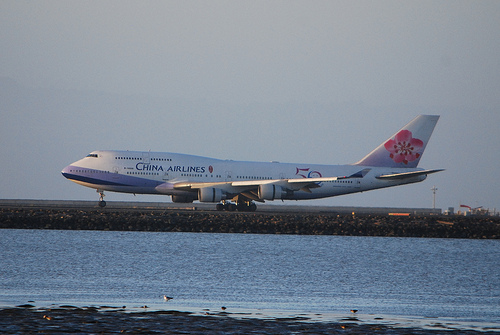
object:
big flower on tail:
[382, 129, 425, 166]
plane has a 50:
[282, 159, 333, 201]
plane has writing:
[118, 151, 228, 189]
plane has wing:
[125, 144, 386, 216]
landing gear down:
[81, 180, 276, 214]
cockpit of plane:
[83, 153, 99, 159]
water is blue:
[106, 233, 204, 301]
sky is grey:
[163, 25, 288, 114]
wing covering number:
[270, 162, 348, 194]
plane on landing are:
[47, 113, 454, 213]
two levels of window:
[87, 154, 298, 184]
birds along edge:
[346, 306, 364, 313]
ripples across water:
[61, 252, 168, 285]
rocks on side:
[10, 208, 34, 231]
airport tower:
[428, 182, 441, 209]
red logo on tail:
[377, 127, 438, 170]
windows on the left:
[60, 139, 131, 199]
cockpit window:
[88, 154, 98, 158]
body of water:
[162, 240, 267, 290]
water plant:
[461, 205, 493, 238]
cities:
[374, 189, 500, 222]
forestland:
[12, 193, 76, 229]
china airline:
[133, 161, 207, 173]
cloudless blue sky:
[105, 16, 286, 131]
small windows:
[114, 156, 118, 160]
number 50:
[294, 166, 324, 188]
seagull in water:
[158, 288, 181, 305]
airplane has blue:
[57, 138, 157, 227]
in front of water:
[37, 127, 142, 300]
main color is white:
[218, 163, 286, 173]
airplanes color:
[396, 132, 411, 140]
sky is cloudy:
[172, 43, 301, 146]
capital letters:
[135, 161, 143, 171]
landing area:
[8, 198, 181, 232]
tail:
[361, 112, 439, 167]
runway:
[3, 206, 497, 231]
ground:
[0, 209, 499, 232]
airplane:
[61, 111, 441, 212]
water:
[5, 236, 492, 304]